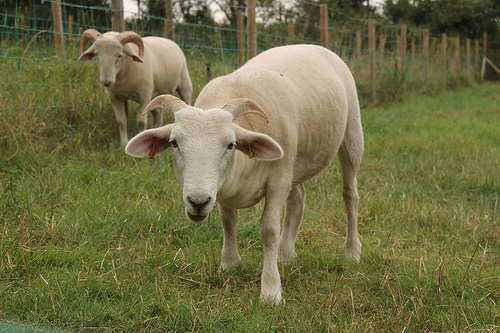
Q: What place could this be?
A: It is a field.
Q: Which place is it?
A: It is a field.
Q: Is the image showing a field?
A: Yes, it is showing a field.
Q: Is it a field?
A: Yes, it is a field.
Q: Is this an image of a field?
A: Yes, it is showing a field.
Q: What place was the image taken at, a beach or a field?
A: It was taken at a field.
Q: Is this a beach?
A: No, it is a field.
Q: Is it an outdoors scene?
A: Yes, it is outdoors.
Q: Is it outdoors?
A: Yes, it is outdoors.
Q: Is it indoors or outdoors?
A: It is outdoors.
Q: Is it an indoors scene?
A: No, it is outdoors.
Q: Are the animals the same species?
A: Yes, all the animals are sheep.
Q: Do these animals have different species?
A: No, all the animals are sheep.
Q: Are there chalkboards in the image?
A: No, there are no chalkboards.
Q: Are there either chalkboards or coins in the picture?
A: No, there are no chalkboards or coins.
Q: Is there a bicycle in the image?
A: No, there are no bicycles.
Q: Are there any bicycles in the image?
A: No, there are no bicycles.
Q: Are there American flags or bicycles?
A: No, there are no bicycles or American flags.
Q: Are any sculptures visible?
A: No, there are no sculptures.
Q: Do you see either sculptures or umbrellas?
A: No, there are no sculptures or umbrellas.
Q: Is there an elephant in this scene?
A: No, there are no elephants.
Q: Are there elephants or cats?
A: No, there are no elephants or cats.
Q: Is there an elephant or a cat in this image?
A: No, there are no cats or elephants.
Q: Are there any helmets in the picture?
A: No, there are no helmets.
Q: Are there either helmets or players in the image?
A: No, there are no helmets or players.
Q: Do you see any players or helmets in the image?
A: No, there are no helmets or players.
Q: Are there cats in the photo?
A: No, there are no cats.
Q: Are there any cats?
A: No, there are no cats.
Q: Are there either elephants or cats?
A: No, there are no cats or elephants.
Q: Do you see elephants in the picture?
A: No, there are no elephants.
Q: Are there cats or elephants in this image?
A: No, there are no elephants or cats.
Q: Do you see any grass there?
A: Yes, there is grass.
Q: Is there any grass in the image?
A: Yes, there is grass.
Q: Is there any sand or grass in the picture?
A: Yes, there is grass.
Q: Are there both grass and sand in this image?
A: No, there is grass but no sand.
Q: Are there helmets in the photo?
A: No, there are no helmets.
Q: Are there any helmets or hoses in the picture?
A: No, there are no helmets or hoses.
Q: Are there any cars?
A: No, there are no cars.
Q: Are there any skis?
A: No, there are no skis.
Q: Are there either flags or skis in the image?
A: No, there are no skis or flags.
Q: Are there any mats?
A: No, there are no mats.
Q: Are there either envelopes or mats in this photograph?
A: No, there are no mats or envelopes.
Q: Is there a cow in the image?
A: No, there are no cows.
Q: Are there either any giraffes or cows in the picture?
A: No, there are no cows or giraffes.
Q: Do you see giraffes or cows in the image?
A: No, there are no cows or giraffes.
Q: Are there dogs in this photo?
A: No, there are no dogs.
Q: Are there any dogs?
A: No, there are no dogs.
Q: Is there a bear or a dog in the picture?
A: No, there are no dogs or bears.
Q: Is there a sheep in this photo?
A: Yes, there is a sheep.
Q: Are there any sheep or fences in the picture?
A: Yes, there is a sheep.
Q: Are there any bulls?
A: No, there are no bulls.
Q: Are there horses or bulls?
A: No, there are no bulls or horses.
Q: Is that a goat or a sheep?
A: That is a sheep.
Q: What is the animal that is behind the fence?
A: The animal is a sheep.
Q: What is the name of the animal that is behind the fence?
A: The animal is a sheep.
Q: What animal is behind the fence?
A: The animal is a sheep.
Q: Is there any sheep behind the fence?
A: Yes, there is a sheep behind the fence.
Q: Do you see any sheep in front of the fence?
A: No, the sheep is behind the fence.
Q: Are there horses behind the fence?
A: No, there is a sheep behind the fence.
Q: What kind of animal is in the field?
A: The animal is a sheep.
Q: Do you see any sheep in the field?
A: Yes, there is a sheep in the field.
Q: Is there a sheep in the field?
A: Yes, there is a sheep in the field.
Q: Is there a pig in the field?
A: No, there is a sheep in the field.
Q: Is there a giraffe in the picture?
A: No, there are no giraffes.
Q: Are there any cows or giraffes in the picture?
A: No, there are no giraffes or cows.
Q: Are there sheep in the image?
A: Yes, there is a sheep.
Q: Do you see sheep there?
A: Yes, there is a sheep.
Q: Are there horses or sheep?
A: Yes, there is a sheep.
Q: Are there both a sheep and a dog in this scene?
A: No, there is a sheep but no dogs.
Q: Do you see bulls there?
A: No, there are no bulls.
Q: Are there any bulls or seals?
A: No, there are no bulls or seals.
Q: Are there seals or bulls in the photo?
A: No, there are no bulls or seals.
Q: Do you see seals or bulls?
A: No, there are no bulls or seals.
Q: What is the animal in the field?
A: The animal is a sheep.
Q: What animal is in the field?
A: The animal is a sheep.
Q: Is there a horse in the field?
A: No, there is a sheep in the field.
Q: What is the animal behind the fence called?
A: The animal is a sheep.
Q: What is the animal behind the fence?
A: The animal is a sheep.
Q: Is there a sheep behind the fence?
A: Yes, there is a sheep behind the fence.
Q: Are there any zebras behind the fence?
A: No, there is a sheep behind the fence.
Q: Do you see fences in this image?
A: Yes, there is a fence.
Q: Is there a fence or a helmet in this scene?
A: Yes, there is a fence.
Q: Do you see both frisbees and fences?
A: No, there is a fence but no frisbees.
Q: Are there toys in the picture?
A: No, there are no toys.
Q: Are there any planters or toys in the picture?
A: No, there are no toys or planters.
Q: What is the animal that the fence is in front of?
A: The animal is a sheep.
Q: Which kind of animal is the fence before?
A: The fence is in front of the sheep.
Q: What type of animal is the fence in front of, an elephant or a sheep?
A: The fence is in front of a sheep.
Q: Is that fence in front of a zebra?
A: No, the fence is in front of a sheep.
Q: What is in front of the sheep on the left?
A: The fence is in front of the sheep.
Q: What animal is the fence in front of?
A: The fence is in front of the sheep.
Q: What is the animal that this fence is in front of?
A: The animal is a sheep.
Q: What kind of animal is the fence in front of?
A: The fence is in front of the sheep.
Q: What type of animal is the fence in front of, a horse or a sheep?
A: The fence is in front of a sheep.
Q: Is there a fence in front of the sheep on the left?
A: Yes, there is a fence in front of the sheep.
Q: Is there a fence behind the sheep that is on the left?
A: No, the fence is in front of the sheep.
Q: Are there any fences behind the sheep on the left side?
A: No, the fence is in front of the sheep.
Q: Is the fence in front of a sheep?
A: Yes, the fence is in front of a sheep.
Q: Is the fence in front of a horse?
A: No, the fence is in front of a sheep.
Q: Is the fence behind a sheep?
A: No, the fence is in front of a sheep.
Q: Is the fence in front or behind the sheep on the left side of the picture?
A: The fence is in front of the sheep.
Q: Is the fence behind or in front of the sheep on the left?
A: The fence is in front of the sheep.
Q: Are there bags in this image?
A: No, there are no bags.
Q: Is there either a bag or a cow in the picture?
A: No, there are no bags or cows.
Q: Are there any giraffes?
A: No, there are no giraffes.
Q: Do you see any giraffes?
A: No, there are no giraffes.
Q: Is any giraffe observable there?
A: No, there are no giraffes.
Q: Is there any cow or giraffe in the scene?
A: No, there are no giraffes or cows.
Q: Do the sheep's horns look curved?
A: Yes, the horns are curved.